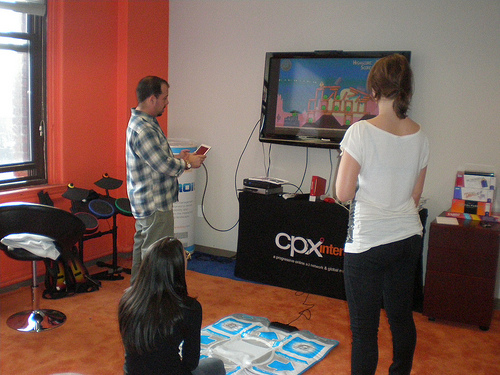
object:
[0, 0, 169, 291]
wall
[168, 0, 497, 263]
wall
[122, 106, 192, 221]
man's shirt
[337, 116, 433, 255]
woman's shirt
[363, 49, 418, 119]
woman's hair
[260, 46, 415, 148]
tv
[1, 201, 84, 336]
chair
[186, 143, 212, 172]
controller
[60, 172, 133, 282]
drumset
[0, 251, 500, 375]
carpet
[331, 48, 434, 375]
people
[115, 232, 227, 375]
woman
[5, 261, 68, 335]
base on chair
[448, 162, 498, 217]
box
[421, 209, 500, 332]
stand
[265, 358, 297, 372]
arrow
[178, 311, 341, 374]
game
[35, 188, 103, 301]
guitars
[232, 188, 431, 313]
table cloth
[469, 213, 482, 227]
books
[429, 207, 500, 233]
counter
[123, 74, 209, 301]
man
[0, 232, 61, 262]
white shirt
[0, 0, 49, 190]
window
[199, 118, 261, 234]
cable